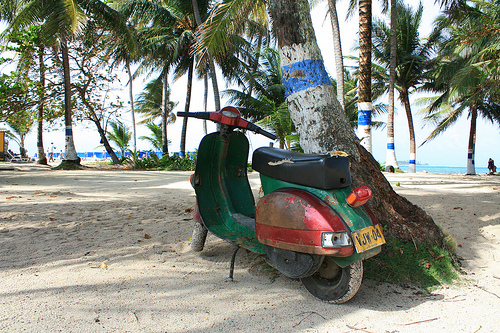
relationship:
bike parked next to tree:
[175, 106, 386, 305] [187, 6, 469, 288]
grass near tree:
[407, 172, 456, 202] [348, 21, 385, 160]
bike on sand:
[175, 106, 386, 305] [34, 247, 456, 320]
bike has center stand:
[175, 106, 386, 305] [227, 246, 241, 282]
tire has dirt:
[299, 256, 363, 304] [345, 264, 364, 298]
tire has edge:
[299, 256, 363, 304] [285, 271, 305, 284]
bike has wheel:
[169, 99, 387, 308] [182, 196, 220, 260]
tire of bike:
[190, 221, 208, 252] [175, 106, 386, 305]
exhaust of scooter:
[314, 260, 367, 276] [183, 96, 411, 320]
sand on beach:
[1, 172, 498, 332] [0, 160, 253, 327]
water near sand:
[378, 157, 498, 177] [387, 169, 498, 316]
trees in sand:
[340, 5, 487, 179] [53, 200, 148, 300]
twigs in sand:
[293, 253, 490, 330] [28, 195, 149, 328]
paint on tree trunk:
[274, 54, 331, 101] [290, 97, 462, 284]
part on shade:
[82, 205, 120, 241] [223, 303, 311, 330]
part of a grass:
[136, 159, 156, 161] [61, 72, 360, 237]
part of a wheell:
[341, 285, 351, 288] [350, 267, 364, 289]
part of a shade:
[72, 233, 95, 246] [3, 166, 217, 285]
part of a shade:
[258, 313, 285, 328] [93, 218, 120, 251]